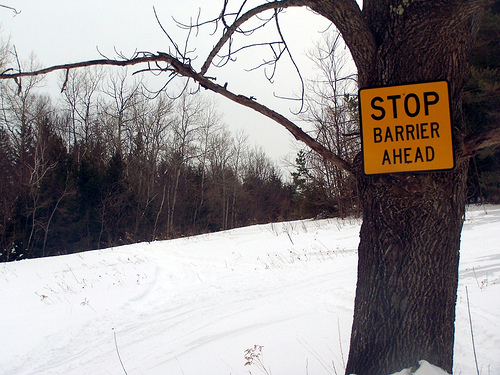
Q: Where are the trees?
A: Background.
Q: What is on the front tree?
A: Sign.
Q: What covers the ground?
A: Snow.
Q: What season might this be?
A: Winter.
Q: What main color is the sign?
A: Orange.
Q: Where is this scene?
A: Ski slope.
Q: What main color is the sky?
A: White.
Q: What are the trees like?
A: Leafless.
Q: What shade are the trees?
A: Dark.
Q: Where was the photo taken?
A: In a field.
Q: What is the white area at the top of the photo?
A: The sky.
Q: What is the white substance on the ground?
A: Snow.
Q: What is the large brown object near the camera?
A: A tree.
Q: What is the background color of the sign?
A: Yellow.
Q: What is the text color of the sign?
A: Black.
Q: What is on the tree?
A: A sign.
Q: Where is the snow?
A: On the ground.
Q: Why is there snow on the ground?
A: It is winter.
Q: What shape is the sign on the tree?
A: Square.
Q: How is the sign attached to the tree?
A: Nails.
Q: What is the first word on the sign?
A: STOP.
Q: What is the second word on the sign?
A: BARRIER.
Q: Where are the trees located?
A: In a forest.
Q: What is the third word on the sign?
A: AHEAD.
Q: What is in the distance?
A: The forest.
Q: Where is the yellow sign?
A: On the tree.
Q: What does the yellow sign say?
A: STOP BARRIER AHEAD.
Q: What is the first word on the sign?
A: Stop.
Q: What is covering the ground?
A: Snow.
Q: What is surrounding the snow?
A: Trees.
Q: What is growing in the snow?
A: Grass.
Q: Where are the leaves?
A: On the trees.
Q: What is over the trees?
A: Sky.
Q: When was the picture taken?
A: Daytime.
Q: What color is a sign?
A: Yellow.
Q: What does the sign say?
A: "STOP BARRIER AHEAD".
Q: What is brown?
A: Tree.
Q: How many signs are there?
A: One.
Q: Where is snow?
A: On the ground.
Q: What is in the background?
A: Many trees.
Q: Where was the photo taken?
A: At a ski park.